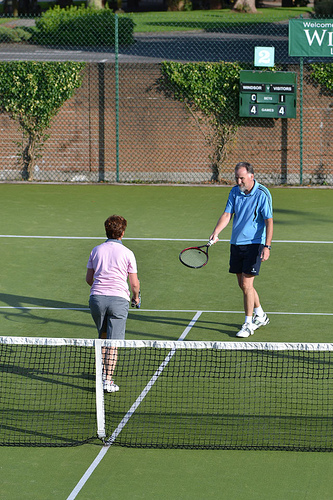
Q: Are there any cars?
A: No, there are no cars.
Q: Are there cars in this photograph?
A: No, there are no cars.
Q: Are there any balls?
A: No, there are no balls.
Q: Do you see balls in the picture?
A: No, there are no balls.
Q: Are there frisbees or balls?
A: No, there are no balls or frisbees.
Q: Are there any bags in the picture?
A: No, there are no bags.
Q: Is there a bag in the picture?
A: No, there are no bags.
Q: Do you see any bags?
A: No, there are no bags.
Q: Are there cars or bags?
A: No, there are no bags or cars.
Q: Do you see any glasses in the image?
A: No, there are no glasses.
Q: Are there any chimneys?
A: No, there are no chimneys.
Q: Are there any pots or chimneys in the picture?
A: No, there are no chimneys or pots.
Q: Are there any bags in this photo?
A: No, there are no bags.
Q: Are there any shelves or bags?
A: No, there are no bags or shelves.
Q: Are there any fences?
A: Yes, there is a fence.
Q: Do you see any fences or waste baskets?
A: Yes, there is a fence.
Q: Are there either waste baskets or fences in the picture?
A: Yes, there is a fence.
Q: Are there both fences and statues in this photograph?
A: No, there is a fence but no statues.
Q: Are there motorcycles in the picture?
A: No, there are no motorcycles.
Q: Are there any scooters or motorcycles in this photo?
A: No, there are no motorcycles or scooters.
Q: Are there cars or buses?
A: No, there are no cars or buses.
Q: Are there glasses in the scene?
A: No, there are no glasses.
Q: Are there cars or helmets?
A: No, there are no cars or helmets.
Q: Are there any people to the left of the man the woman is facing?
A: Yes, there is a person to the left of the man.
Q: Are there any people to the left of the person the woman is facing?
A: Yes, there is a person to the left of the man.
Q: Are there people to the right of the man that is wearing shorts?
A: No, the person is to the left of the man.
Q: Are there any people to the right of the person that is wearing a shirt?
A: No, the person is to the left of the man.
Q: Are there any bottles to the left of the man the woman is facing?
A: No, there is a person to the left of the man.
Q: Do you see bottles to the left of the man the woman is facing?
A: No, there is a person to the left of the man.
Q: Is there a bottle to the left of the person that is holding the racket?
A: No, there is a person to the left of the man.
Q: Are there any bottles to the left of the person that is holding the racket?
A: No, there is a person to the left of the man.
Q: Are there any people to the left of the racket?
A: Yes, there is a person to the left of the racket.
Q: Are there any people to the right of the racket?
A: No, the person is to the left of the racket.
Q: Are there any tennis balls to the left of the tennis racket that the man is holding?
A: No, there is a person to the left of the tennis racket.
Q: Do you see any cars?
A: No, there are no cars.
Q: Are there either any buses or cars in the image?
A: No, there are no cars or buses.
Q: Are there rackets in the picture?
A: Yes, there is a racket.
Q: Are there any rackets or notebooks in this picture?
A: Yes, there is a racket.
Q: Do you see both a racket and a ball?
A: No, there is a racket but no balls.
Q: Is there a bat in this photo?
A: No, there are no bats.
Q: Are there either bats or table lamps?
A: No, there are no bats or table lamps.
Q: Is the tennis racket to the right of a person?
A: Yes, the tennis racket is to the right of a person.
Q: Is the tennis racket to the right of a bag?
A: No, the tennis racket is to the right of a person.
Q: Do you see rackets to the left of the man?
A: Yes, there is a racket to the left of the man.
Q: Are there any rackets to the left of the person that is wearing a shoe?
A: Yes, there is a racket to the left of the man.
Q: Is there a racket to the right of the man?
A: No, the racket is to the left of the man.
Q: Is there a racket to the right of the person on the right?
A: No, the racket is to the left of the man.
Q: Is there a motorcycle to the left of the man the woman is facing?
A: No, there is a racket to the left of the man.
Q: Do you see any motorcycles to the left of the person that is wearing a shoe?
A: No, there is a racket to the left of the man.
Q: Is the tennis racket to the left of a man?
A: Yes, the tennis racket is to the left of a man.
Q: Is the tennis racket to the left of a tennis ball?
A: No, the tennis racket is to the left of a man.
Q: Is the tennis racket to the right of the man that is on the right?
A: No, the tennis racket is to the left of the man.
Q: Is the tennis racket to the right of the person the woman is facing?
A: No, the tennis racket is to the left of the man.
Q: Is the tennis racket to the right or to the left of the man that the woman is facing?
A: The tennis racket is to the left of the man.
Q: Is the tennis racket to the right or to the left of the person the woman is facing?
A: The tennis racket is to the left of the man.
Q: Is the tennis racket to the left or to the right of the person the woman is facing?
A: The tennis racket is to the left of the man.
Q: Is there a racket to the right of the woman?
A: Yes, there is a racket to the right of the woman.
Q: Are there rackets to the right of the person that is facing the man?
A: Yes, there is a racket to the right of the woman.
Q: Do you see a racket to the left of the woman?
A: No, the racket is to the right of the woman.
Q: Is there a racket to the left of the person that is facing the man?
A: No, the racket is to the right of the woman.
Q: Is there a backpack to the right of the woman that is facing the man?
A: No, there is a racket to the right of the woman.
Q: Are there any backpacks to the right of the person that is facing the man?
A: No, there is a racket to the right of the woman.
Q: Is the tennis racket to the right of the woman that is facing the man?
A: Yes, the tennis racket is to the right of the woman.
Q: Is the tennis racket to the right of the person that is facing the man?
A: Yes, the tennis racket is to the right of the woman.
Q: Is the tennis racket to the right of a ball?
A: No, the tennis racket is to the right of the woman.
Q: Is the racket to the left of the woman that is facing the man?
A: No, the racket is to the right of the woman.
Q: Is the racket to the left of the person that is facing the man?
A: No, the racket is to the right of the woman.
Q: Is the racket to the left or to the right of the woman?
A: The racket is to the right of the woman.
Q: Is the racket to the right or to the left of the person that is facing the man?
A: The racket is to the right of the woman.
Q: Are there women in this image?
A: Yes, there is a woman.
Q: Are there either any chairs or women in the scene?
A: Yes, there is a woman.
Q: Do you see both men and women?
A: Yes, there are both a woman and a man.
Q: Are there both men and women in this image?
A: Yes, there are both a woman and a man.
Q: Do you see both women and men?
A: Yes, there are both a woman and a man.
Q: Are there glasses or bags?
A: No, there are no bags or glasses.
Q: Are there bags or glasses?
A: No, there are no bags or glasses.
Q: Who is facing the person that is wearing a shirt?
A: The woman is facing the man.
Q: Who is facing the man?
A: The woman is facing the man.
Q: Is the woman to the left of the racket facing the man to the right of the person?
A: Yes, the woman is facing the man.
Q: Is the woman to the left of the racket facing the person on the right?
A: Yes, the woman is facing the man.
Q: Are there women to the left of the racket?
A: Yes, there is a woman to the left of the racket.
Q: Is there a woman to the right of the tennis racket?
A: No, the woman is to the left of the tennis racket.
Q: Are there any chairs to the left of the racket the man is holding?
A: No, there is a woman to the left of the racket.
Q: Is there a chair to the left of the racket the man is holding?
A: No, there is a woman to the left of the racket.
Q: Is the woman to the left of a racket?
A: Yes, the woman is to the left of a racket.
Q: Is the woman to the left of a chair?
A: No, the woman is to the left of a racket.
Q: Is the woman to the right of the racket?
A: No, the woman is to the left of the racket.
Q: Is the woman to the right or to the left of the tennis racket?
A: The woman is to the left of the tennis racket.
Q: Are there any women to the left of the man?
A: Yes, there is a woman to the left of the man.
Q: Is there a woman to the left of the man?
A: Yes, there is a woman to the left of the man.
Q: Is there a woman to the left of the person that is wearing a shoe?
A: Yes, there is a woman to the left of the man.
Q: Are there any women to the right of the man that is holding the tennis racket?
A: No, the woman is to the left of the man.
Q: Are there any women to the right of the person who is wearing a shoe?
A: No, the woman is to the left of the man.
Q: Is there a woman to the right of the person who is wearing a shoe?
A: No, the woman is to the left of the man.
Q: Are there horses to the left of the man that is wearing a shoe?
A: No, there is a woman to the left of the man.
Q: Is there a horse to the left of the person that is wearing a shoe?
A: No, there is a woman to the left of the man.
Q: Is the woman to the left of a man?
A: Yes, the woman is to the left of a man.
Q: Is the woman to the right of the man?
A: No, the woman is to the left of the man.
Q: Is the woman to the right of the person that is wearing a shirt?
A: No, the woman is to the left of the man.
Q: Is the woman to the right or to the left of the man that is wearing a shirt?
A: The woman is to the left of the man.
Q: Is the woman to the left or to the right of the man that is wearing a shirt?
A: The woman is to the left of the man.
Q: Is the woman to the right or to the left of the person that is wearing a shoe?
A: The woman is to the left of the man.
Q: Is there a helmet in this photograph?
A: No, there are no helmets.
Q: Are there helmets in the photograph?
A: No, there are no helmets.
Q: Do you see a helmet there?
A: No, there are no helmets.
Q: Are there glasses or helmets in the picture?
A: No, there are no helmets or glasses.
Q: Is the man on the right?
A: Yes, the man is on the right of the image.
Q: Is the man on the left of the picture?
A: No, the man is on the right of the image.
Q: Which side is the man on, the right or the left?
A: The man is on the right of the image.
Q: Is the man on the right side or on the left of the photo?
A: The man is on the right of the image.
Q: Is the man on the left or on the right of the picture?
A: The man is on the right of the image.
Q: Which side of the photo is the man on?
A: The man is on the right of the image.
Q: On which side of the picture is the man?
A: The man is on the right of the image.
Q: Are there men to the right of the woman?
A: Yes, there is a man to the right of the woman.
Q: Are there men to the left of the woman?
A: No, the man is to the right of the woman.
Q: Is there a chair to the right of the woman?
A: No, there is a man to the right of the woman.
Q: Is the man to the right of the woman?
A: Yes, the man is to the right of the woman.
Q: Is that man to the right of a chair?
A: No, the man is to the right of the woman.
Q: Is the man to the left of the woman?
A: No, the man is to the right of the woman.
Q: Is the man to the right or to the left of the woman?
A: The man is to the right of the woman.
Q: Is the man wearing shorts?
A: Yes, the man is wearing shorts.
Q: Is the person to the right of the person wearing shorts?
A: Yes, the man is wearing shorts.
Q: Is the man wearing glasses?
A: No, the man is wearing shorts.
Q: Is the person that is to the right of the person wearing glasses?
A: No, the man is wearing shorts.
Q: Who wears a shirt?
A: The man wears a shirt.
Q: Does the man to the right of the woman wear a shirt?
A: Yes, the man wears a shirt.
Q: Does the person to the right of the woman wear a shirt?
A: Yes, the man wears a shirt.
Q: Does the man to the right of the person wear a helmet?
A: No, the man wears a shirt.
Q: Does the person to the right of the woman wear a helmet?
A: No, the man wears a shirt.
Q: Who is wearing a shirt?
A: The man is wearing a shirt.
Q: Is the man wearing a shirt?
A: Yes, the man is wearing a shirt.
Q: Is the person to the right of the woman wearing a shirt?
A: Yes, the man is wearing a shirt.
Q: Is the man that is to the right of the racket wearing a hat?
A: No, the man is wearing a shirt.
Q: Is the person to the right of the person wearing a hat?
A: No, the man is wearing a shirt.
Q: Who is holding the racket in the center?
A: The man is holding the tennis racket.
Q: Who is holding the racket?
A: The man is holding the tennis racket.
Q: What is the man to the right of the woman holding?
A: The man is holding the tennis racket.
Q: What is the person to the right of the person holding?
A: The man is holding the tennis racket.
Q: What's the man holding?
A: The man is holding the tennis racket.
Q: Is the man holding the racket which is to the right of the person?
A: Yes, the man is holding the racket.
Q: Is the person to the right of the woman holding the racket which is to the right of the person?
A: Yes, the man is holding the racket.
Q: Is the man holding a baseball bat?
A: No, the man is holding the racket.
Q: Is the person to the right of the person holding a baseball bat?
A: No, the man is holding the racket.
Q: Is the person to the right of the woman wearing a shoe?
A: Yes, the man is wearing a shoe.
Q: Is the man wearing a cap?
A: No, the man is wearing a shoe.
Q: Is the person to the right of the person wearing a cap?
A: No, the man is wearing a shoe.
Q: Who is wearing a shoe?
A: The man is wearing a shoe.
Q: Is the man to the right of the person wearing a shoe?
A: Yes, the man is wearing a shoe.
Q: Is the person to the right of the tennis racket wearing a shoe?
A: Yes, the man is wearing a shoe.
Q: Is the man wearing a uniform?
A: No, the man is wearing a shoe.